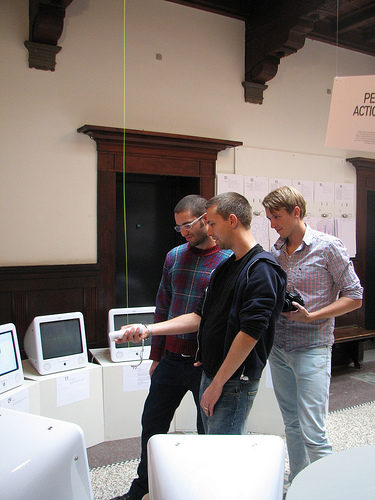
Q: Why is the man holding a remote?
A: He is using it.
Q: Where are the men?
A: In a room.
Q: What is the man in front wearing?
A: A jacket.